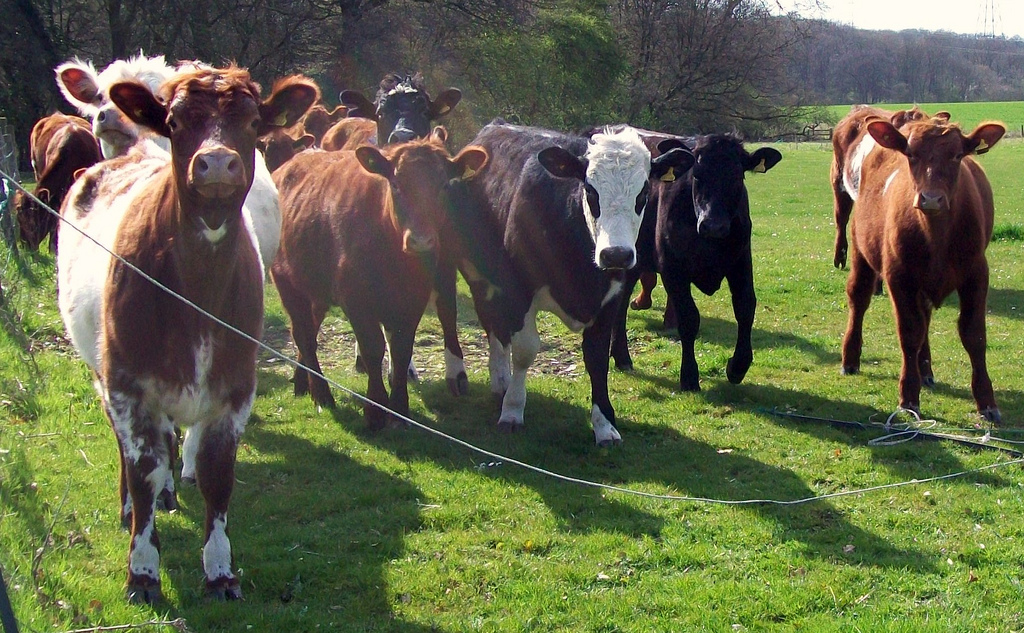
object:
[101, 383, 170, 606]
leg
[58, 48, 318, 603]
cow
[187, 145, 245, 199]
snout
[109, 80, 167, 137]
ear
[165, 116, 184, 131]
eye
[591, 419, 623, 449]
hoof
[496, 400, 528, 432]
hoof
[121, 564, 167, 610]
hoof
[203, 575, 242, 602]
hoof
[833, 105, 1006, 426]
cow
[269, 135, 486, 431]
cow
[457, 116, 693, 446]
cow